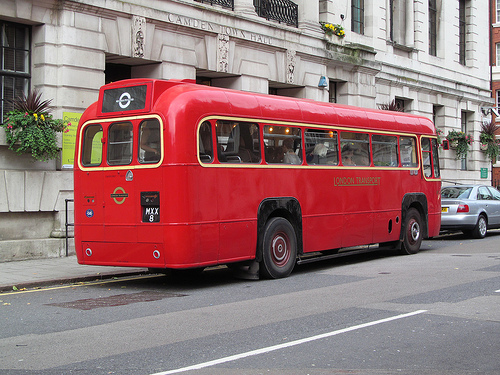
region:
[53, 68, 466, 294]
RED BUS ON STREET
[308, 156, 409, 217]
BUS BELONGS TO LONDON TRANSPORT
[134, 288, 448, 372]
WHITE LINE SEPARATING LANES ON STREET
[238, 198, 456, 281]
TIRES WITH RED AND SILVER HUB CAPS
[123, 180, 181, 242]
TAG ON BUS READS MXX 8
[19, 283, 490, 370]
STREET IS PAVED WITH ASPHALT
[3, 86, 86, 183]
PLANT WITH FLOWERS IN WINDOW BOX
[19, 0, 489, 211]
WHITE ORNATE BUILDING ON LEFT SIDE OF BUS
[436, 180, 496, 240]
SILVER AUTOMOBILE IN FRONT OF BUS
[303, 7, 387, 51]
YELLOW FLOWERS IN WINDOW BOX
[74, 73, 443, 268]
red bus on street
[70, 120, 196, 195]
yellow frame around windows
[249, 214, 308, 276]
black wheels on bus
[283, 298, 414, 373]
white line on street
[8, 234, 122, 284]
grey sidewalk behind bus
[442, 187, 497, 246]
grey car behind bus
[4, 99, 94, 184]
green plant next to bus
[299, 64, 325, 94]
blue light above bus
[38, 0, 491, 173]
grey building behind bus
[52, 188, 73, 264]
black rail behind bus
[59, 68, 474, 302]
a red bus on the side of the road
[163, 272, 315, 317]
black asphalt of the road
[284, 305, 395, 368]
white line painted on the road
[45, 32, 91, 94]
grey stone cloumn of a building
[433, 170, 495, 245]
grey car parked on the side of the road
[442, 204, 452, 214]
yellow license plate of the grey car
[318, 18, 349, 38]
flowers over the entryway of the building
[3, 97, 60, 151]
pants growing on the window sill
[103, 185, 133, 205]
gold and black logo on the red bus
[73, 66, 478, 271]
red bus parked on the side of the road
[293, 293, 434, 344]
line painted in the road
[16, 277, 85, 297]
curb at the edge of the road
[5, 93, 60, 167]
plants in the box below the window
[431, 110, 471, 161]
hanging plants outside the building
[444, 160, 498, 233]
car parked in front of the bus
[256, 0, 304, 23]
metal railing on the building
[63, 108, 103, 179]
sign on the side of the building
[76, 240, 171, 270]
two red tail lights on the bus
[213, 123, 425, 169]
windows on the bus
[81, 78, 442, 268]
The bus is red.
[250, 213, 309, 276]
The tire is black.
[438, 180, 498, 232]
The car is parked.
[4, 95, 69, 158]
The flowers are by the window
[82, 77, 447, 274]
The bus is parked.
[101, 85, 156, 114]
The sign is black.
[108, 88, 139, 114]
The lettering is white.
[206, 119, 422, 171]
People are sitting on the bus.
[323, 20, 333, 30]
a yellow flower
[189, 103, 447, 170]
The windows are on the side of the bus